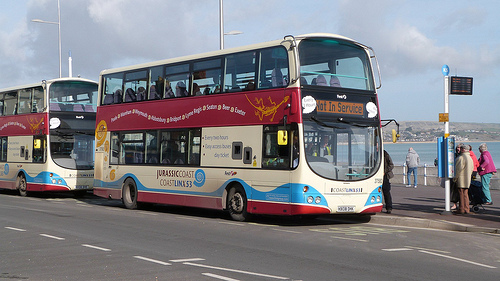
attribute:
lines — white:
[8, 219, 282, 281]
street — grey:
[7, 186, 499, 280]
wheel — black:
[226, 181, 250, 222]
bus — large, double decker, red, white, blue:
[95, 35, 387, 223]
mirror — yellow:
[274, 128, 292, 147]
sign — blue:
[437, 135, 459, 182]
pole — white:
[442, 74, 450, 210]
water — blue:
[379, 139, 499, 172]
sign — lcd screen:
[314, 97, 367, 117]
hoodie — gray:
[405, 152, 426, 173]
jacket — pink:
[474, 151, 498, 173]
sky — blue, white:
[5, 1, 499, 124]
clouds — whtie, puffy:
[363, 20, 465, 71]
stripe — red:
[96, 187, 317, 213]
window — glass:
[159, 130, 187, 168]